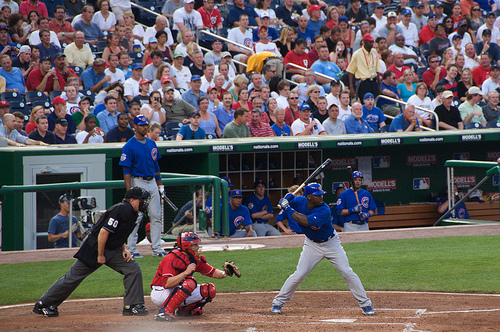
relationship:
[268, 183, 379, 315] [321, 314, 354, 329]
ball player standing at home plate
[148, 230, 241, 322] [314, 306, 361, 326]
ball player crouching behind home plate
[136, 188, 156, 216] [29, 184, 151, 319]
face guard on ball player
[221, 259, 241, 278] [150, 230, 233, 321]
mitt on catcher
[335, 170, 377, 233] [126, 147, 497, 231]
ball player in dugout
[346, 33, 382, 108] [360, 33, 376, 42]
man wearing hat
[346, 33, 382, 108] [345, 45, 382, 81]
man wearing shirt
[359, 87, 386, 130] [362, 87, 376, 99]
man wearing hat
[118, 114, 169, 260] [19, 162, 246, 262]
ball player standing in dugout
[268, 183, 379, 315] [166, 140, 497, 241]
ball player in dugout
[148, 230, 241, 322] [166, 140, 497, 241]
ball player in dugout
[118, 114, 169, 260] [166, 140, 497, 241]
ball player in dugout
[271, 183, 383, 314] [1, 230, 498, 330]
ball player standing on side of field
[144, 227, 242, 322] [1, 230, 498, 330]
ball player standing on side of field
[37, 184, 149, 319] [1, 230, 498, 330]
ball player standing on side of field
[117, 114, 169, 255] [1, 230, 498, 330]
ball player standing on side of field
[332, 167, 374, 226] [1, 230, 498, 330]
ball player standing on side of field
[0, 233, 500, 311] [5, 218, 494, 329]
grass on field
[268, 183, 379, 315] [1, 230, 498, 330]
ball player playing on field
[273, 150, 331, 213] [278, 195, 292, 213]
baseball bat in hand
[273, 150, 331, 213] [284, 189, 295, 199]
baseball bat in hand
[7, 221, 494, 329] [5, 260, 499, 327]
grass on field